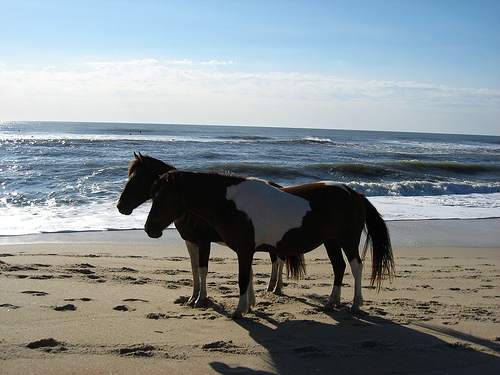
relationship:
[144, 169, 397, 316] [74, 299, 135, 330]
horse on beach